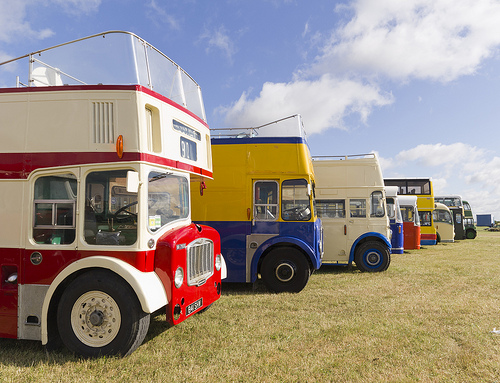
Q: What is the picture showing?
A: It is showing a field.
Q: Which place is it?
A: It is a field.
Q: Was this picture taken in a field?
A: Yes, it was taken in a field.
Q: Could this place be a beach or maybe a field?
A: It is a field.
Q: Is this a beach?
A: No, it is a field.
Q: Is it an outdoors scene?
A: Yes, it is outdoors.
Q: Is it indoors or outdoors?
A: It is outdoors.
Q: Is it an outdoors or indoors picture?
A: It is outdoors.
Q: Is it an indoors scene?
A: No, it is outdoors.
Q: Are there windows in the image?
A: Yes, there is a window.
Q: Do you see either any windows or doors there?
A: Yes, there is a window.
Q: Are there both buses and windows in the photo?
A: Yes, there are both a window and a bus.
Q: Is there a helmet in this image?
A: No, there are no helmets.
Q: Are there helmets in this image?
A: No, there are no helmets.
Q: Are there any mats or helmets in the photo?
A: No, there are no helmets or mats.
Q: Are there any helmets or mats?
A: No, there are no helmets or mats.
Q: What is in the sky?
A: The clouds are in the sky.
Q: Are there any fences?
A: No, there are no fences.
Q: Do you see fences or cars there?
A: No, there are no fences or cars.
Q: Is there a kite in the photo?
A: No, there are no kites.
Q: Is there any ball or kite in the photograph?
A: No, there are no kites or balls.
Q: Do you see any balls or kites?
A: No, there are no kites or balls.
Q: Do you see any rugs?
A: No, there are no rugs.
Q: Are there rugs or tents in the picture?
A: No, there are no rugs or tents.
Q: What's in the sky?
A: The clouds are in the sky.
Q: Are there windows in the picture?
A: Yes, there is a window.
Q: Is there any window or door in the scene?
A: Yes, there is a window.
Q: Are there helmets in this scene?
A: No, there are no helmets.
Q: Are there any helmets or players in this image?
A: No, there are no helmets or players.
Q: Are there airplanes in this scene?
A: No, there are no airplanes.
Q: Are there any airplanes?
A: No, there are no airplanes.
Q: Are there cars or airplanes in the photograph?
A: No, there are no airplanes or cars.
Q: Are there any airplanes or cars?
A: No, there are no airplanes or cars.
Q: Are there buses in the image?
A: Yes, there are buses.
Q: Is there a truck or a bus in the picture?
A: Yes, there are buses.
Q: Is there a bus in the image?
A: Yes, there are buses.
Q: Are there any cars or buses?
A: Yes, there are buses.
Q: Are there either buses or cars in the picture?
A: Yes, there are buses.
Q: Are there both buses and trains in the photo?
A: No, there are buses but no trains.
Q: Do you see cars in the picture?
A: No, there are no cars.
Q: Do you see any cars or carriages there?
A: No, there are no cars or carriages.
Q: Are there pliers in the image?
A: No, there are no pliers.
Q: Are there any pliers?
A: No, there are no pliers.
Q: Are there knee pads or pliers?
A: No, there are no pliers or knee pads.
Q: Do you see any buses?
A: Yes, there are buses.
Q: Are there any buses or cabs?
A: Yes, there are buses.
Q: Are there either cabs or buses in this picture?
A: Yes, there are buses.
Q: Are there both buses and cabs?
A: No, there are buses but no taxis.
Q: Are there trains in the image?
A: No, there are no trains.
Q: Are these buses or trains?
A: These are buses.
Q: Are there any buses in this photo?
A: Yes, there are buses.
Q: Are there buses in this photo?
A: Yes, there are buses.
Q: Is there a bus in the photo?
A: Yes, there are buses.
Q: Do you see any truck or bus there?
A: Yes, there are buses.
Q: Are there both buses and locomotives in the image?
A: No, there are buses but no locomotives.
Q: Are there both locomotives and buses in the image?
A: No, there are buses but no locomotives.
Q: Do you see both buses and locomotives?
A: No, there are buses but no locomotives.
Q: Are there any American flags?
A: No, there are no American flags.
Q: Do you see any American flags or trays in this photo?
A: No, there are no American flags or trays.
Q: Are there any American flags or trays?
A: No, there are no American flags or trays.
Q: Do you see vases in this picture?
A: No, there are no vases.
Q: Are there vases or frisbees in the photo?
A: No, there are no vases or frisbees.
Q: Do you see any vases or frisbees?
A: No, there are no vases or frisbees.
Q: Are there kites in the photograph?
A: No, there are no kites.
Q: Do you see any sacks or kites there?
A: No, there are no kites or sacks.